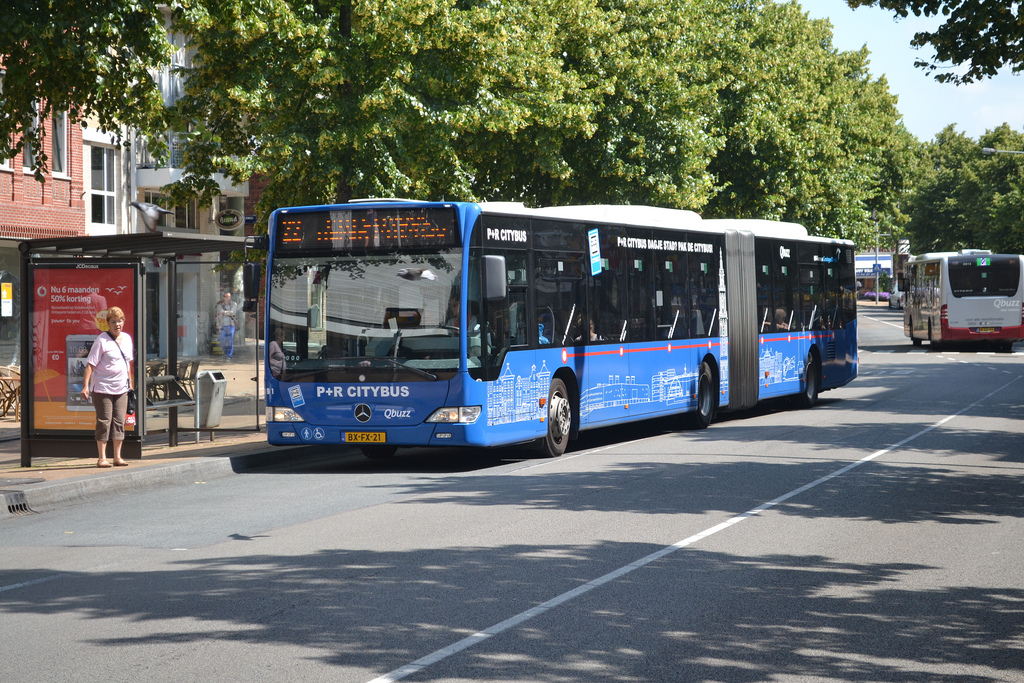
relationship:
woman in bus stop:
[79, 303, 146, 471] [14, 232, 261, 470]